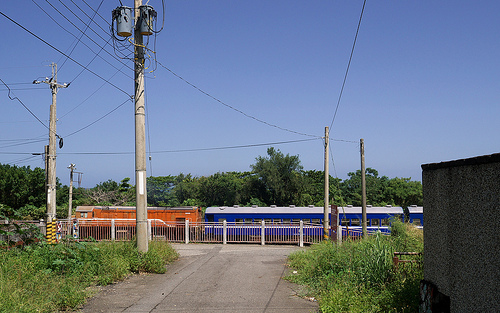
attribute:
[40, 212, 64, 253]
poles — yellow, black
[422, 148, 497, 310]
concrete building — grey, black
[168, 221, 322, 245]
fence — white, long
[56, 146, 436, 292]
train — blue, white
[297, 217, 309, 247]
post — white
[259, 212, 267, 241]
post — white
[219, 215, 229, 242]
post — white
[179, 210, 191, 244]
post — white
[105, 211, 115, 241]
post — white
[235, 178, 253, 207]
clock — big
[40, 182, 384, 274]
fence — long, white, grey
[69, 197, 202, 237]
train — orange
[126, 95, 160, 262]
pole — electric, gray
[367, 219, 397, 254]
clock — big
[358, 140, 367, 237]
post — here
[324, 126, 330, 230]
post — here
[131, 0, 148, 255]
post — here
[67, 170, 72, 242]
post — here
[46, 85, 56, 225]
post — here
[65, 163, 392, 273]
train — orange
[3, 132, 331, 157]
power line — these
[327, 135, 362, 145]
power line — these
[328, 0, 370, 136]
power line — these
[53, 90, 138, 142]
power line — these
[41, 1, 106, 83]
power line — these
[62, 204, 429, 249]
train — here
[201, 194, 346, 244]
cars — blue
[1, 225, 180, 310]
plants — green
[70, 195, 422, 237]
train — orange, blue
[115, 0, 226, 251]
pole — grey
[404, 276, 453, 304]
clock — big